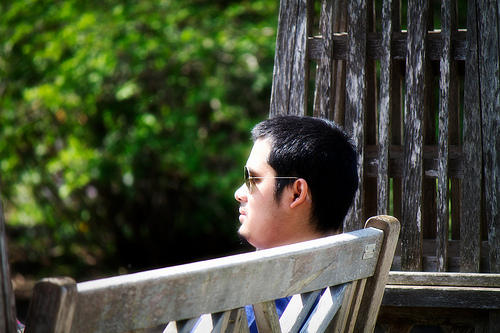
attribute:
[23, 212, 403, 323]
bench — wooden, illuminated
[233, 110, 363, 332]
man — sitting, illuminated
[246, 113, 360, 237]
hair — black, blue, short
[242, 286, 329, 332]
shirt — blue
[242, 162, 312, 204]
sunglasses — wire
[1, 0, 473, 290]
trees — green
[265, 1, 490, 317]
fence — chipped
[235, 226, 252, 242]
goattee — black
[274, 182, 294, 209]
sideburns — black